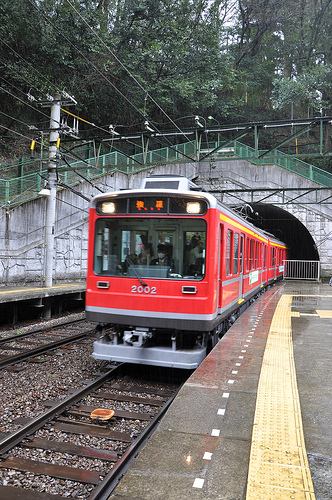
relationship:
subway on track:
[94, 138, 301, 355] [13, 333, 190, 498]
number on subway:
[115, 271, 182, 308] [85, 174, 291, 371]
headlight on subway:
[177, 279, 205, 298] [85, 174, 291, 371]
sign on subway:
[132, 187, 184, 215] [85, 174, 291, 371]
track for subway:
[13, 333, 190, 498] [85, 174, 291, 371]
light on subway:
[96, 199, 126, 229] [85, 174, 291, 371]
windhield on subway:
[96, 196, 212, 298] [85, 174, 291, 371]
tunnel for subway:
[232, 178, 330, 262] [85, 174, 291, 371]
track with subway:
[13, 333, 190, 498] [85, 174, 291, 371]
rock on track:
[24, 373, 39, 388] [13, 333, 190, 498]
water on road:
[291, 341, 330, 391] [273, 304, 312, 421]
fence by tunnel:
[265, 246, 312, 285] [232, 178, 330, 262]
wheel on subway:
[203, 319, 226, 356] [85, 174, 291, 371]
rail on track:
[24, 384, 82, 435] [13, 333, 190, 498]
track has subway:
[13, 333, 190, 498] [85, 174, 291, 371]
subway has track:
[85, 174, 291, 371] [13, 333, 190, 498]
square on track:
[78, 397, 129, 423] [13, 333, 190, 498]